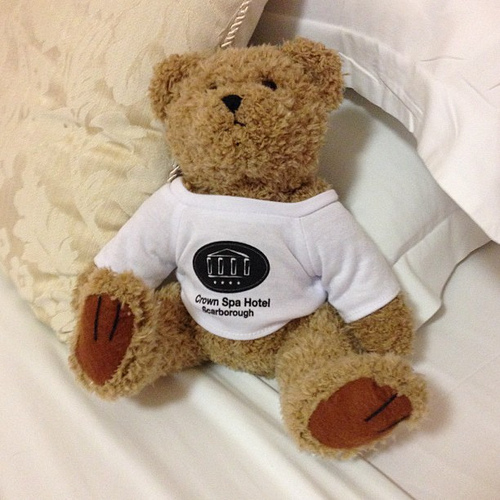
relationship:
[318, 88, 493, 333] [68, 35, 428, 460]
pillow under teddy bear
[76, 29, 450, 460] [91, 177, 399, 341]
bear wearing shirt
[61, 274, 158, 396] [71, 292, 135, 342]
foot with toes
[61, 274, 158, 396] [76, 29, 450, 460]
foot on bear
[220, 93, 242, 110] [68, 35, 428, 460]
nose on teddy bear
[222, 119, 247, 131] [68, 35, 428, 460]
mouth on teddy bear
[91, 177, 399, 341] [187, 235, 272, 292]
shirt has picture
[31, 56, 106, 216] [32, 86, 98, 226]
pillow has pattern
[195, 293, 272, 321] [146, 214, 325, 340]
lettering on shirt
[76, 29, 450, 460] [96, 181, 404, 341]
bear wearing shirt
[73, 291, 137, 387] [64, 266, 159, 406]
bottom of foot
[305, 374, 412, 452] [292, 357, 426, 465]
bottom of feet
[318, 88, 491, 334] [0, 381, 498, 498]
pillow on bed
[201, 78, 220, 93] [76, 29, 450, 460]
eye on bear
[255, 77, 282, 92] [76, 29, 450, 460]
eye on bear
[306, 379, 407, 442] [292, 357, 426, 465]
sole on feet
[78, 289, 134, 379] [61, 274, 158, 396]
sole on foot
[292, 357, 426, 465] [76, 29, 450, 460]
feet of bear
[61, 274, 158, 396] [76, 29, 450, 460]
foot of bear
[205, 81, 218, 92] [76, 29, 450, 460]
eye of bear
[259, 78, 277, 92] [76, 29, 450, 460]
eye of bear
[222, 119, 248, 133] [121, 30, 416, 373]
mouth on teddy bear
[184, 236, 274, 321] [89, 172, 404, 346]
graphic on shirt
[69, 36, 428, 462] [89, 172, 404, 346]
bear has shirt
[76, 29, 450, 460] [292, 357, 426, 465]
bear has feet